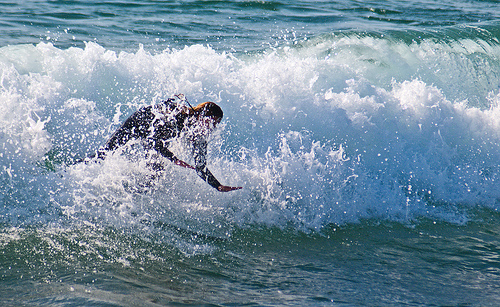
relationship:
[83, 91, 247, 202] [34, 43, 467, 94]
person in a wave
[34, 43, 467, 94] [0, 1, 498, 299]
wave in ocean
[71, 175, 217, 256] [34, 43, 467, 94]
surfboard under wave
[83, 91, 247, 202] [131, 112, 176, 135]
woman wears a black suit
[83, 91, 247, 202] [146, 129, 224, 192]
woman extended arm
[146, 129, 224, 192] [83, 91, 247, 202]
arm of woman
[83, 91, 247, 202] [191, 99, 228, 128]
woman has hair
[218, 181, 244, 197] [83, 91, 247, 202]
hand of a woman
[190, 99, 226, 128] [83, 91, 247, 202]
head of a woman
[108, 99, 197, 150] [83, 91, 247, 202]
body of woman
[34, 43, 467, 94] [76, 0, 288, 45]
wave on water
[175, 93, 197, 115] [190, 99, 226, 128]
string on head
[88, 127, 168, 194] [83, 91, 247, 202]
legs of a woman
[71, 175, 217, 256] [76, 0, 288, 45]
surfboard under water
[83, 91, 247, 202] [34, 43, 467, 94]
person on a wave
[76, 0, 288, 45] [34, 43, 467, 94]
water of wave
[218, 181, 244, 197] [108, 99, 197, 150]
hand in front of body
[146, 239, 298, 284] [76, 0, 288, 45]
ripples in water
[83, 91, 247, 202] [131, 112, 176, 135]
person wearing a black suit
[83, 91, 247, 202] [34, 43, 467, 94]
person engulfed by wave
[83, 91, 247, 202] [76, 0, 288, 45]
person in water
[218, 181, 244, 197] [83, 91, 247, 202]
hand of person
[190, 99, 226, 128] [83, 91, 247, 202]
head of person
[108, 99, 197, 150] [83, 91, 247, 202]
body of person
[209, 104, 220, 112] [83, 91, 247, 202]
hair of person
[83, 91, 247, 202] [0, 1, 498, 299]
person in ocean